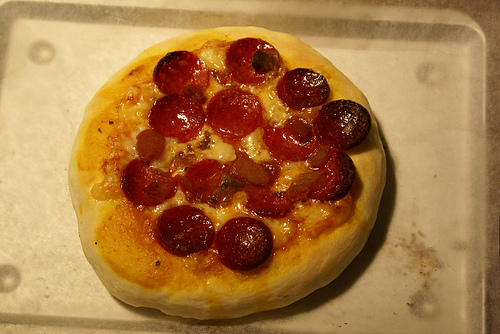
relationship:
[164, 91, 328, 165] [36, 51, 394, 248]
pepperoni on pizza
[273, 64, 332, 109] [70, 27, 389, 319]
pepperoni on pizza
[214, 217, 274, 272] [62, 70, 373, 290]
pepperoni on pizza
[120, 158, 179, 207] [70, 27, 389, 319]
pepperoni on pizza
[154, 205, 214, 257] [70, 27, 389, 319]
pepperoni on pizza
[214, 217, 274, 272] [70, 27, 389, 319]
pepperoni on pizza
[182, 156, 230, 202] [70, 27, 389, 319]
pepperoni on pizza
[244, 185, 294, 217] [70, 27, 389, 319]
pepperoni on pizza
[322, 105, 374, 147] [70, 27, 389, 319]
pepperoni on pizza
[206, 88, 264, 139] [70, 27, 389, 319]
pepperoni on pizza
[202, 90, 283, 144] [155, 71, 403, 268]
pepperoni on pizza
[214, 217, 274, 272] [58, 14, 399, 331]
pepperoni on pizza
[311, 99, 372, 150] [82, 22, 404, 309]
pepperoni on pizza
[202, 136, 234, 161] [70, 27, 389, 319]
cheese on pizza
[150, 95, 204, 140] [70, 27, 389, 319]
pepperoni on pizza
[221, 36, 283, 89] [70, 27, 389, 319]
pepperoni on pizza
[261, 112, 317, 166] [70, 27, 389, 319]
pepperoni on pizza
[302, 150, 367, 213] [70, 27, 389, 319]
pepperoni on pizza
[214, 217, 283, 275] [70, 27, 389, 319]
pepperoni on pizza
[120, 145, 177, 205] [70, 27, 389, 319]
pepperoni on pizza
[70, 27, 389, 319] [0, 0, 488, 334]
pizza on pizza pan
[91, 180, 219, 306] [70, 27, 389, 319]
crust on pizza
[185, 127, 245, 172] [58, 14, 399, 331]
cheese on pizza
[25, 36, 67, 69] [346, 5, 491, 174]
indention in pizza pan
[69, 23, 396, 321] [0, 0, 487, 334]
food on metal pan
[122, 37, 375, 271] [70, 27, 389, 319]
pepperoni on pizza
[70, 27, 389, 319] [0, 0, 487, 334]
pizza on metal pan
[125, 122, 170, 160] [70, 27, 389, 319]
onion on pizza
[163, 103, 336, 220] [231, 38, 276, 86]
cheese covering pepperoni